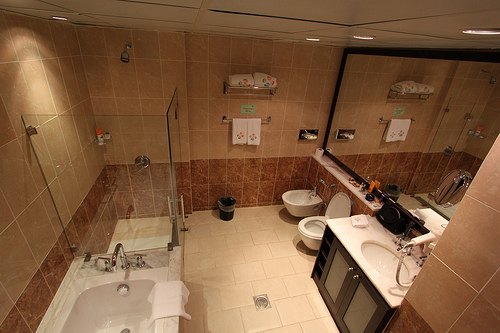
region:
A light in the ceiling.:
[461, 25, 498, 37]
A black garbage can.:
[216, 191, 239, 222]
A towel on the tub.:
[144, 278, 194, 323]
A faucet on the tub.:
[108, 240, 132, 272]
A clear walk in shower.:
[18, 82, 186, 253]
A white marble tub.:
[36, 240, 186, 331]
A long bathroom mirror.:
[319, 43, 498, 237]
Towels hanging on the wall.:
[220, 113, 272, 148]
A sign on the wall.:
[238, 103, 258, 116]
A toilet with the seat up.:
[296, 188, 351, 253]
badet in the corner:
[273, 178, 325, 213]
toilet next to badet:
[288, 197, 364, 244]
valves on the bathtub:
[96, 240, 147, 270]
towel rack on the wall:
[218, 110, 275, 142]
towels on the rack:
[227, 115, 263, 145]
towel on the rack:
[232, 116, 246, 145]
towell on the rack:
[250, 119, 260, 145]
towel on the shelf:
[232, 71, 257, 88]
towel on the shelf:
[257, 69, 277, 87]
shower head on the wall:
[120, 43, 134, 60]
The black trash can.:
[219, 197, 236, 222]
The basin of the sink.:
[362, 243, 404, 282]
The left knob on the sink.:
[397, 233, 403, 245]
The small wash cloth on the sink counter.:
[352, 216, 364, 226]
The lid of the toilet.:
[326, 192, 346, 217]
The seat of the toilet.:
[301, 215, 328, 235]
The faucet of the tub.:
[107, 245, 125, 270]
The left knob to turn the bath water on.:
[97, 250, 116, 272]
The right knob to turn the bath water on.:
[130, 252, 145, 263]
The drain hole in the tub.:
[115, 323, 137, 331]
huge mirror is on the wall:
[343, 53, 494, 210]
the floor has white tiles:
[216, 240, 281, 331]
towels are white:
[223, 108, 270, 143]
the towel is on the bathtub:
[140, 278, 202, 330]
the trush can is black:
[214, 191, 236, 218]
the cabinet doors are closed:
[315, 249, 381, 327]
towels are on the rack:
[227, 68, 277, 87]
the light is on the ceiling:
[291, 28, 378, 55]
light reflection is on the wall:
[21, 40, 87, 131]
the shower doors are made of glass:
[32, 110, 185, 249]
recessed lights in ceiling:
[3, 3, 495, 43]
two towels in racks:
[218, 114, 270, 147]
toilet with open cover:
[296, 191, 352, 253]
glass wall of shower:
[21, 91, 183, 270]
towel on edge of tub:
[148, 281, 192, 326]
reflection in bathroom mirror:
[324, 49, 496, 214]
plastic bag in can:
[216, 194, 235, 221]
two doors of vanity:
[316, 238, 389, 331]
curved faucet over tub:
[109, 240, 129, 273]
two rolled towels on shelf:
[221, 71, 278, 97]